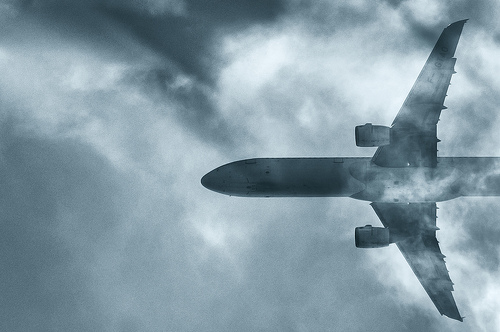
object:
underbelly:
[270, 164, 421, 194]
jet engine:
[349, 160, 463, 184]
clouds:
[114, 53, 249, 164]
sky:
[0, 0, 499, 330]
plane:
[199, 17, 500, 324]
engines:
[354, 224, 414, 249]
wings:
[368, 200, 463, 323]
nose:
[201, 158, 288, 199]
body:
[201, 155, 499, 204]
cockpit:
[201, 158, 273, 196]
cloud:
[7, 1, 291, 95]